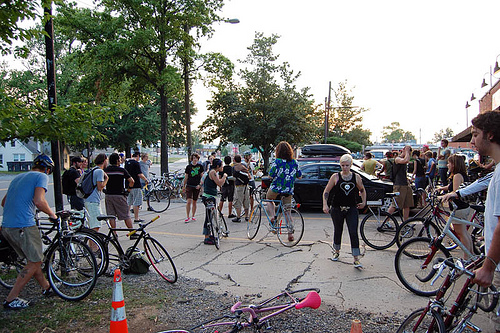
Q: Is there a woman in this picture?
A: Yes, there is a woman.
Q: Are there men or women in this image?
A: Yes, there is a woman.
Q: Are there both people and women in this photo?
A: Yes, there are both a woman and a person.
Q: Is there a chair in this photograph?
A: No, there are no chairs.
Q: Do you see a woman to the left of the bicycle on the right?
A: Yes, there is a woman to the left of the bicycle.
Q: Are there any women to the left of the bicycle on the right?
A: Yes, there is a woman to the left of the bicycle.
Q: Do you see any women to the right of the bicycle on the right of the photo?
A: No, the woman is to the left of the bicycle.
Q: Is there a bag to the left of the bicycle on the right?
A: No, there is a woman to the left of the bicycle.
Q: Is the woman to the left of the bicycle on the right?
A: Yes, the woman is to the left of the bicycle.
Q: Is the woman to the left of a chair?
A: No, the woman is to the left of the bicycle.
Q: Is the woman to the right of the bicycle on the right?
A: No, the woman is to the left of the bicycle.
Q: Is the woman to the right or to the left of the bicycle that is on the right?
A: The woman is to the left of the bicycle.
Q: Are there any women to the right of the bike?
A: Yes, there is a woman to the right of the bike.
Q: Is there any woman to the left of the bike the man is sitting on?
A: No, the woman is to the right of the bike.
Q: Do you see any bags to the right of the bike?
A: No, there is a woman to the right of the bike.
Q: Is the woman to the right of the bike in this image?
A: Yes, the woman is to the right of the bike.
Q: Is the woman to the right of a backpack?
A: No, the woman is to the right of the bike.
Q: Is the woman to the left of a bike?
A: No, the woman is to the right of a bike.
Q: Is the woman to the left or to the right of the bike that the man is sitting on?
A: The woman is to the right of the bike.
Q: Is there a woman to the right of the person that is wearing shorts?
A: Yes, there is a woman to the right of the person.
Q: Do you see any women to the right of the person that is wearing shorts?
A: Yes, there is a woman to the right of the person.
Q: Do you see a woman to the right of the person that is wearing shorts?
A: Yes, there is a woman to the right of the person.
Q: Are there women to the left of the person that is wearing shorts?
A: No, the woman is to the right of the person.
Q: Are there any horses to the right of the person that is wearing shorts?
A: No, there is a woman to the right of the person.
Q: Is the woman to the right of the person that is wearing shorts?
A: Yes, the woman is to the right of the person.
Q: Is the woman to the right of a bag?
A: No, the woman is to the right of the person.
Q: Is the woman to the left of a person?
A: No, the woman is to the right of a person.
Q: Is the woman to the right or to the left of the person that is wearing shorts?
A: The woman is to the right of the person.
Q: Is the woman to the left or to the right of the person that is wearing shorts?
A: The woman is to the right of the person.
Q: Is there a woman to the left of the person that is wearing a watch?
A: Yes, there is a woman to the left of the person.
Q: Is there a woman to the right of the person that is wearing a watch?
A: No, the woman is to the left of the person.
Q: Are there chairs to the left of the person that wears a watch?
A: No, there is a woman to the left of the person.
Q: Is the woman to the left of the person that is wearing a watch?
A: Yes, the woman is to the left of the person.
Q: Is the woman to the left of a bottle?
A: No, the woman is to the left of the person.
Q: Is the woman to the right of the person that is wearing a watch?
A: No, the woman is to the left of the person.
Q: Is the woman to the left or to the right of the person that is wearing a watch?
A: The woman is to the left of the person.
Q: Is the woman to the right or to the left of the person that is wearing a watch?
A: The woman is to the left of the person.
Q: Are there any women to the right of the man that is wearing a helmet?
A: Yes, there is a woman to the right of the man.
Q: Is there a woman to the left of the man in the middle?
A: No, the woman is to the right of the man.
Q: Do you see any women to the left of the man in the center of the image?
A: No, the woman is to the right of the man.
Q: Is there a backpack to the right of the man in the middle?
A: No, there is a woman to the right of the man.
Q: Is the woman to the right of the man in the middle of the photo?
A: Yes, the woman is to the right of the man.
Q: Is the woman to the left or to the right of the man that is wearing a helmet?
A: The woman is to the right of the man.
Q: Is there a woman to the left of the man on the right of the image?
A: Yes, there is a woman to the left of the man.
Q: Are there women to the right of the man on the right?
A: No, the woman is to the left of the man.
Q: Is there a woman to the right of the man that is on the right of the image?
A: No, the woman is to the left of the man.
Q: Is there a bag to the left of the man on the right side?
A: No, there is a woman to the left of the man.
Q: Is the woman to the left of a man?
A: Yes, the woman is to the left of a man.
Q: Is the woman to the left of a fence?
A: No, the woman is to the left of a man.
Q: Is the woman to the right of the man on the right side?
A: No, the woman is to the left of the man.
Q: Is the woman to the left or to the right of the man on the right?
A: The woman is to the left of the man.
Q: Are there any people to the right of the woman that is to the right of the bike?
A: Yes, there is a person to the right of the woman.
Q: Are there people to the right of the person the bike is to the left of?
A: Yes, there is a person to the right of the woman.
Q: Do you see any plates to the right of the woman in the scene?
A: No, there is a person to the right of the woman.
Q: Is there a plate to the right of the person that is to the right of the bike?
A: No, there is a person to the right of the woman.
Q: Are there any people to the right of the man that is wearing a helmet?
A: Yes, there is a person to the right of the man.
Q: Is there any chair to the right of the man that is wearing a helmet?
A: No, there is a person to the right of the man.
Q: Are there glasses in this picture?
A: No, there are no glasses.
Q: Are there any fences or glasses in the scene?
A: No, there are no glasses or fences.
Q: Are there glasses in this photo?
A: No, there are no glasses.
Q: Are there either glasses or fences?
A: No, there are no glasses or fences.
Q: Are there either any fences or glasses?
A: No, there are no glasses or fences.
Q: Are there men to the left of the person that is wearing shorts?
A: Yes, there is a man to the left of the person.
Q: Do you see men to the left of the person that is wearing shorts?
A: Yes, there is a man to the left of the person.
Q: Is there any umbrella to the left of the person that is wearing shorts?
A: No, there is a man to the left of the person.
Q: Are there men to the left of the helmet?
A: No, the man is to the right of the helmet.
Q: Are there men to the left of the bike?
A: Yes, there is a man to the left of the bike.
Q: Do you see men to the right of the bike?
A: No, the man is to the left of the bike.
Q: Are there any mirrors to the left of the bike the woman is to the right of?
A: No, there is a man to the left of the bike.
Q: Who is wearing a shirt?
A: The man is wearing a shirt.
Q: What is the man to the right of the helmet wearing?
A: The man is wearing a shirt.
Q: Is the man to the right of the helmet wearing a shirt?
A: Yes, the man is wearing a shirt.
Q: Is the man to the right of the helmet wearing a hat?
A: No, the man is wearing a shirt.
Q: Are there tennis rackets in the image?
A: No, there are no tennis rackets.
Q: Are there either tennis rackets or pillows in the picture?
A: No, there are no tennis rackets or pillows.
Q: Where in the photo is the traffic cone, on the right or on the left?
A: The traffic cone is on the left of the image.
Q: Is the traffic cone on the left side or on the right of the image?
A: The traffic cone is on the left of the image.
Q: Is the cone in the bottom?
A: Yes, the cone is in the bottom of the image.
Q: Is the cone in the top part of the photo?
A: No, the cone is in the bottom of the image.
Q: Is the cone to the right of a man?
A: Yes, the cone is to the right of a man.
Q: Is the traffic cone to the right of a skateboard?
A: No, the traffic cone is to the right of a man.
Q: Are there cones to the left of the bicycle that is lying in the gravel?
A: Yes, there is a cone to the left of the bicycle.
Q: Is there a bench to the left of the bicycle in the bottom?
A: No, there is a cone to the left of the bicycle.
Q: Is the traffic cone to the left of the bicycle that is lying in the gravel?
A: Yes, the traffic cone is to the left of the bicycle.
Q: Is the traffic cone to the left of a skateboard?
A: No, the traffic cone is to the left of the bicycle.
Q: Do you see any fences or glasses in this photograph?
A: No, there are no fences or glasses.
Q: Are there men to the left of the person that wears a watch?
A: Yes, there is a man to the left of the person.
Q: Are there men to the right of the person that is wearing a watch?
A: No, the man is to the left of the person.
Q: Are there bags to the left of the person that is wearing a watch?
A: No, there is a man to the left of the person.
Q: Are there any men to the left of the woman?
A: Yes, there is a man to the left of the woman.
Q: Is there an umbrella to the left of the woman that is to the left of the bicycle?
A: No, there is a man to the left of the woman.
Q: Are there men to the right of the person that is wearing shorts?
A: Yes, there is a man to the right of the person.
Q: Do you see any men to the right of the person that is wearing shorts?
A: Yes, there is a man to the right of the person.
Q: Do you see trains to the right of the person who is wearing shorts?
A: No, there is a man to the right of the person.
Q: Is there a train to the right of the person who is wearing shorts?
A: No, there is a man to the right of the person.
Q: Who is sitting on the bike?
A: The man is sitting on the bike.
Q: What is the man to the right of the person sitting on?
A: The man is sitting on the bike.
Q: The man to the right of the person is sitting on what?
A: The man is sitting on the bike.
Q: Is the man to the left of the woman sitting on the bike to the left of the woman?
A: Yes, the man is sitting on the bike.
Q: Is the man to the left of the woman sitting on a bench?
A: No, the man is sitting on the bike.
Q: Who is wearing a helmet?
A: The man is wearing a helmet.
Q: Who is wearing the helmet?
A: The man is wearing a helmet.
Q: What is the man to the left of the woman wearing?
A: The man is wearing a helmet.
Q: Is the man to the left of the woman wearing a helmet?
A: Yes, the man is wearing a helmet.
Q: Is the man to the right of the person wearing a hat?
A: No, the man is wearing a helmet.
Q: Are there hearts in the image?
A: Yes, there is a heart.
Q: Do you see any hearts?
A: Yes, there is a heart.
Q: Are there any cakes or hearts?
A: Yes, there is a heart.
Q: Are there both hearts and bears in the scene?
A: No, there is a heart but no bears.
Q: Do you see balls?
A: No, there are no balls.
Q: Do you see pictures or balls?
A: No, there are no balls or pictures.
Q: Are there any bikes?
A: Yes, there is a bike.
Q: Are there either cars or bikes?
A: Yes, there is a bike.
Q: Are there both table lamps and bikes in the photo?
A: No, there is a bike but no table lamps.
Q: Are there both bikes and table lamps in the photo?
A: No, there is a bike but no table lamps.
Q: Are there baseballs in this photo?
A: No, there are no baseballs.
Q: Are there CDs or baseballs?
A: No, there are no baseballs or cds.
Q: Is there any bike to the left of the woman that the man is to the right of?
A: Yes, there is a bike to the left of the woman.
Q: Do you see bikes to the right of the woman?
A: No, the bike is to the left of the woman.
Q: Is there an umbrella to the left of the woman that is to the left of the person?
A: No, there is a bike to the left of the woman.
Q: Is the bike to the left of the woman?
A: Yes, the bike is to the left of the woman.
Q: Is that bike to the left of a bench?
A: No, the bike is to the left of the woman.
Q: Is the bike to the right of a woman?
A: No, the bike is to the left of a woman.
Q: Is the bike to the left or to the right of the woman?
A: The bike is to the left of the woman.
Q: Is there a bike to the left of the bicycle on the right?
A: Yes, there is a bike to the left of the bicycle.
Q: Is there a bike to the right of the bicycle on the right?
A: No, the bike is to the left of the bicycle.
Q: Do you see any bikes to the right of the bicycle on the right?
A: No, the bike is to the left of the bicycle.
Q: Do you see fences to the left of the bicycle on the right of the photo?
A: No, there is a bike to the left of the bicycle.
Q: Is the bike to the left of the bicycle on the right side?
A: Yes, the bike is to the left of the bicycle.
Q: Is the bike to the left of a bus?
A: No, the bike is to the left of the bicycle.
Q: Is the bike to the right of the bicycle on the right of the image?
A: No, the bike is to the left of the bicycle.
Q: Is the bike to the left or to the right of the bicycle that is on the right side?
A: The bike is to the left of the bicycle.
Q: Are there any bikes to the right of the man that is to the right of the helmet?
A: Yes, there is a bike to the right of the man.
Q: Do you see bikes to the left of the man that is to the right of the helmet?
A: No, the bike is to the right of the man.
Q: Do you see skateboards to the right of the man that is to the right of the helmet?
A: No, there is a bike to the right of the man.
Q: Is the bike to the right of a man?
A: Yes, the bike is to the right of a man.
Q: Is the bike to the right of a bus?
A: No, the bike is to the right of a man.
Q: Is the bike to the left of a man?
A: No, the bike is to the right of a man.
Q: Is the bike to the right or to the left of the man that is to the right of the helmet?
A: The bike is to the right of the man.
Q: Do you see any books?
A: No, there are no books.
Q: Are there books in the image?
A: No, there are no books.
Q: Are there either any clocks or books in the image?
A: No, there are no books or clocks.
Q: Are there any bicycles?
A: Yes, there is a bicycle.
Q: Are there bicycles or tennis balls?
A: Yes, there is a bicycle.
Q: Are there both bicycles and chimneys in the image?
A: No, there is a bicycle but no chimneys.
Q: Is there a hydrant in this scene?
A: No, there are no fire hydrants.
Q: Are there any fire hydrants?
A: No, there are no fire hydrants.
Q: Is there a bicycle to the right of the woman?
A: Yes, there is a bicycle to the right of the woman.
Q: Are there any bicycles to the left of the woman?
A: No, the bicycle is to the right of the woman.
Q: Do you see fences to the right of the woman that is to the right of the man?
A: No, there is a bicycle to the right of the woman.